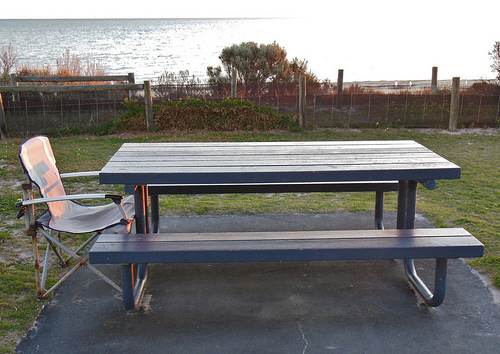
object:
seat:
[46, 194, 137, 234]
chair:
[14, 134, 143, 310]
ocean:
[2, 18, 495, 87]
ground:
[62, 215, 497, 309]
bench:
[139, 182, 399, 231]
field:
[0, 129, 500, 354]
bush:
[204, 41, 317, 92]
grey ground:
[20, 205, 499, 353]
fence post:
[295, 69, 310, 127]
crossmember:
[6, 69, 136, 84]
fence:
[7, 82, 495, 138]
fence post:
[141, 77, 156, 132]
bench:
[90, 227, 485, 313]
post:
[431, 66, 436, 92]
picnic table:
[87, 140, 485, 314]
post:
[336, 69, 343, 107]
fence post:
[446, 77, 464, 128]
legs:
[28, 229, 131, 303]